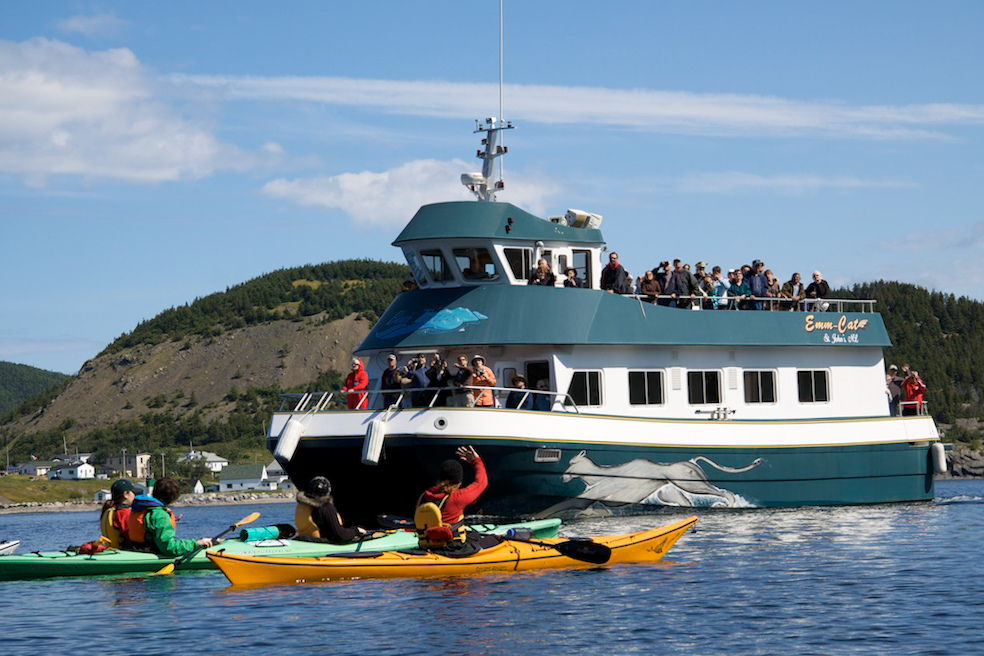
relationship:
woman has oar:
[126, 479, 214, 555] [157, 511, 265, 579]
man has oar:
[408, 448, 492, 558] [157, 511, 265, 579]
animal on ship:
[549, 442, 762, 517] [263, 116, 952, 518]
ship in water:
[263, 116, 952, 518] [1, 483, 983, 653]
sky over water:
[0, 3, 983, 369] [1, 483, 983, 653]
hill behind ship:
[31, 238, 422, 467] [263, 116, 952, 518]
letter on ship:
[802, 314, 818, 332] [263, 116, 952, 518]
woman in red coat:
[126, 479, 214, 555] [341, 358, 372, 399]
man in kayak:
[408, 448, 492, 558] [207, 518, 700, 593]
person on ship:
[465, 353, 502, 405] [263, 116, 952, 518]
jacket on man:
[126, 496, 204, 559] [408, 448, 492, 558]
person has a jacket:
[465, 353, 502, 405] [126, 496, 204, 559]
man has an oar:
[408, 448, 492, 558] [157, 511, 265, 579]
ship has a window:
[263, 116, 952, 518] [682, 369, 721, 401]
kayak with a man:
[207, 518, 700, 593] [408, 448, 492, 558]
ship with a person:
[263, 116, 952, 518] [465, 353, 502, 405]